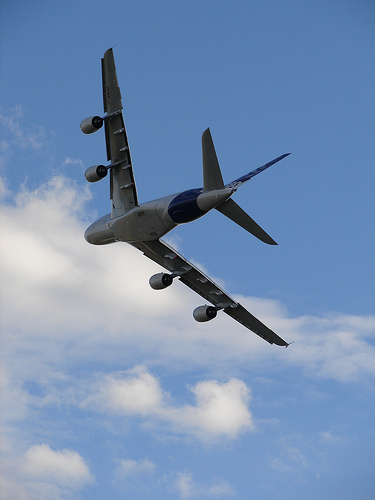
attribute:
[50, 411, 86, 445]
clouds — white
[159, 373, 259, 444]
cloud — white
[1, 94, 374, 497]
clouds — white 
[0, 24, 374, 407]
sky — blue 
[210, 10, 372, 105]
sky — blue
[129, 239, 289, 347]
wing — plane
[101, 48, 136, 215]
wing — plane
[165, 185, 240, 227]
tail — blue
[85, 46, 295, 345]
plane — turning, white 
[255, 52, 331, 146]
sky — blue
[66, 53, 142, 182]
wing — plane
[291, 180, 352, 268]
clouds — white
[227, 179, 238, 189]
writing — white 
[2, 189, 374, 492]
clouds — white 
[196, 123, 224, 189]
wing — rear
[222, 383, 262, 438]
clouds — white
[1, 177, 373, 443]
clouds — white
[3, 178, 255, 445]
clouds — white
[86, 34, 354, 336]
plane — blue 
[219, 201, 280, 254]
right wing — rear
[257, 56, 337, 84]
sky — blue 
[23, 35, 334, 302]
sky — blue 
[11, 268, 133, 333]
clouds — white 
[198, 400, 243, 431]
clouds — white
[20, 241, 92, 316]
clouds — white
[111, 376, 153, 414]
clouds — white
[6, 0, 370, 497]
sky — blue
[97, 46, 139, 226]
wing — plane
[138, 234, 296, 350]
wing — plane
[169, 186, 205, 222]
stripe — blue